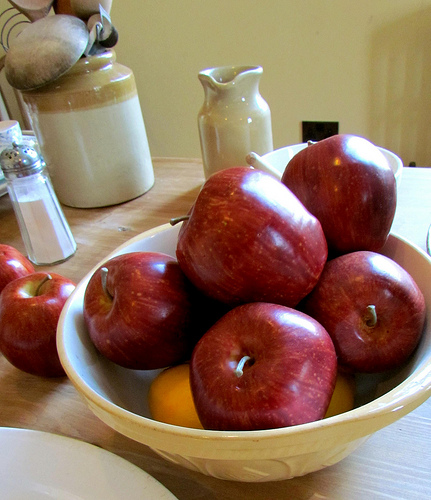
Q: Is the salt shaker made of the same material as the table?
A: No, the salt shaker is made of glass and the table is made of wood.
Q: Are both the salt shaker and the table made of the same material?
A: No, the salt shaker is made of glass and the table is made of wood.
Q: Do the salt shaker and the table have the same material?
A: No, the salt shaker is made of glass and the table is made of wood.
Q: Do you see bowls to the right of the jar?
A: Yes, there is a bowl to the right of the jar.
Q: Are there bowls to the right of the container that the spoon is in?
A: Yes, there is a bowl to the right of the jar.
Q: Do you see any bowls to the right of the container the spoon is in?
A: Yes, there is a bowl to the right of the jar.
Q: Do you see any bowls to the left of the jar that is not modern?
A: No, the bowl is to the right of the jar.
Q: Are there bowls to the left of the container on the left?
A: No, the bowl is to the right of the jar.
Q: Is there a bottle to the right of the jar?
A: No, there is a bowl to the right of the jar.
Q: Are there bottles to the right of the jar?
A: No, there is a bowl to the right of the jar.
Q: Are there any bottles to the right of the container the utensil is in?
A: No, there is a bowl to the right of the jar.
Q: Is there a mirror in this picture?
A: No, there are no mirrors.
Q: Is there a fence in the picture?
A: No, there are no fences.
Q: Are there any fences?
A: No, there are no fences.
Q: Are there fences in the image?
A: No, there are no fences.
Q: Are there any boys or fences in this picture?
A: No, there are no fences or boys.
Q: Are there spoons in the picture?
A: Yes, there is a spoon.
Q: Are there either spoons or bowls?
A: Yes, there is a spoon.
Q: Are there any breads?
A: No, there are no breads.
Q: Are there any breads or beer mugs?
A: No, there are no breads or beer mugs.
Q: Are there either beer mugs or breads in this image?
A: No, there are no breads or beer mugs.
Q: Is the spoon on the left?
A: Yes, the spoon is on the left of the image.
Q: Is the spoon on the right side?
A: No, the spoon is on the left of the image.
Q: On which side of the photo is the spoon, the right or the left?
A: The spoon is on the left of the image.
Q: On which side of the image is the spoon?
A: The spoon is on the left of the image.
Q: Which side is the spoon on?
A: The spoon is on the left of the image.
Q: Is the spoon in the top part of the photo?
A: Yes, the spoon is in the top of the image.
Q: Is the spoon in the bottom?
A: No, the spoon is in the top of the image.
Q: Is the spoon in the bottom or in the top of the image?
A: The spoon is in the top of the image.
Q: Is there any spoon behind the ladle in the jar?
A: Yes, there is a spoon behind the ladle.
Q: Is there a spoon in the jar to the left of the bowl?
A: Yes, there is a spoon in the jar.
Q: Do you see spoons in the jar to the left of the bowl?
A: Yes, there is a spoon in the jar.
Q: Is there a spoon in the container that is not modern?
A: Yes, there is a spoon in the jar.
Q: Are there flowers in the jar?
A: No, there is a spoon in the jar.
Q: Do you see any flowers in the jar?
A: No, there is a spoon in the jar.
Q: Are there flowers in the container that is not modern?
A: No, there is a spoon in the jar.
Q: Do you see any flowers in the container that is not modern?
A: No, there is a spoon in the jar.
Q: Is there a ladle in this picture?
A: Yes, there is a ladle.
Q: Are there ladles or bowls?
A: Yes, there is a ladle.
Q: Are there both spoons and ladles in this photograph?
A: Yes, there are both a ladle and a spoon.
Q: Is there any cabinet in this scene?
A: No, there are no cabinets.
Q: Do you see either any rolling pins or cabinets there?
A: No, there are no cabinets or rolling pins.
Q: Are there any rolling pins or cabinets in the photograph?
A: No, there are no cabinets or rolling pins.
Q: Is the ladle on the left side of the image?
A: Yes, the ladle is on the left of the image.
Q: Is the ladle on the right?
A: No, the ladle is on the left of the image.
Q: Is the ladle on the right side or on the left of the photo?
A: The ladle is on the left of the image.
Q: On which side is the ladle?
A: The ladle is on the left of the image.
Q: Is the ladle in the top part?
A: Yes, the ladle is in the top of the image.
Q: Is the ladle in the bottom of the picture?
A: No, the ladle is in the top of the image.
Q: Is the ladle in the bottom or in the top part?
A: The ladle is in the top of the image.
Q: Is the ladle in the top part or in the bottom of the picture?
A: The ladle is in the top of the image.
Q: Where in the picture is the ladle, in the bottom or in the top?
A: The ladle is in the top of the image.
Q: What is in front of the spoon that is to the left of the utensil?
A: The ladle is in front of the spoon.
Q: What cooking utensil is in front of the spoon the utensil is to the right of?
A: The cooking utensil is a ladle.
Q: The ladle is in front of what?
A: The ladle is in front of the spoon.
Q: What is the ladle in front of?
A: The ladle is in front of the spoon.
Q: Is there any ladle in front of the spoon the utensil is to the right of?
A: Yes, there is a ladle in front of the spoon.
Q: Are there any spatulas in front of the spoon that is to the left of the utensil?
A: No, there is a ladle in front of the spoon.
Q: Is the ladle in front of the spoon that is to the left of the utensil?
A: Yes, the ladle is in front of the spoon.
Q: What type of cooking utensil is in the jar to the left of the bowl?
A: The cooking utensil is a ladle.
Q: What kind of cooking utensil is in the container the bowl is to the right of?
A: The cooking utensil is a ladle.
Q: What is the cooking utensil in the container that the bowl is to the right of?
A: The cooking utensil is a ladle.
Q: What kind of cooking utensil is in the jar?
A: The cooking utensil is a ladle.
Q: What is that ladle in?
A: The ladle is in the jar.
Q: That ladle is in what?
A: The ladle is in the jar.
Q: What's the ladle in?
A: The ladle is in the jar.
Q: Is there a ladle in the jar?
A: Yes, there is a ladle in the jar.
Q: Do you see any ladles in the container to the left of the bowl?
A: Yes, there is a ladle in the jar.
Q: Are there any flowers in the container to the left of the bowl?
A: No, there is a ladle in the jar.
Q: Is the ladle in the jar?
A: Yes, the ladle is in the jar.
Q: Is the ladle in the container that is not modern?
A: Yes, the ladle is in the jar.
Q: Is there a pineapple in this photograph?
A: No, there are no pineapples.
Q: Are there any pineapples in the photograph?
A: No, there are no pineapples.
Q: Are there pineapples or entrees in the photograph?
A: No, there are no pineapples or entrees.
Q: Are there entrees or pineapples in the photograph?
A: No, there are no pineapples or entrees.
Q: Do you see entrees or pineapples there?
A: No, there are no pineapples or entrees.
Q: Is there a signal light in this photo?
A: No, there are no traffic lights.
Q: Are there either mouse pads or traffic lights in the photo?
A: No, there are no traffic lights or mouse pads.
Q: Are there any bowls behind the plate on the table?
A: Yes, there is a bowl behind the plate.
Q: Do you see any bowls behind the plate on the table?
A: Yes, there is a bowl behind the plate.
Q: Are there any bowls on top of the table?
A: Yes, there is a bowl on top of the table.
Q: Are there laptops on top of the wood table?
A: No, there is a bowl on top of the table.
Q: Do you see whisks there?
A: Yes, there is a whisk.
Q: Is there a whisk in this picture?
A: Yes, there is a whisk.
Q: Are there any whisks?
A: Yes, there is a whisk.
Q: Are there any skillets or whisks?
A: Yes, there is a whisk.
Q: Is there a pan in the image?
A: No, there are no pans.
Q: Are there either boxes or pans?
A: No, there are no pans or boxes.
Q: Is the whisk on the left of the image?
A: Yes, the whisk is on the left of the image.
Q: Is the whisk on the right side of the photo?
A: No, the whisk is on the left of the image.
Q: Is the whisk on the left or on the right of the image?
A: The whisk is on the left of the image.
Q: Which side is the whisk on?
A: The whisk is on the left of the image.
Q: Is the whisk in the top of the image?
A: Yes, the whisk is in the top of the image.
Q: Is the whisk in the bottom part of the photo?
A: No, the whisk is in the top of the image.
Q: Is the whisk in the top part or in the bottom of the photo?
A: The whisk is in the top of the image.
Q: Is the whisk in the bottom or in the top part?
A: The whisk is in the top of the image.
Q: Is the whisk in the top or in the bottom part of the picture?
A: The whisk is in the top of the image.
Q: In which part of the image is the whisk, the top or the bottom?
A: The whisk is in the top of the image.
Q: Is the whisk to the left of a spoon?
A: Yes, the whisk is to the left of a spoon.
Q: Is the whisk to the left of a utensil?
A: Yes, the whisk is to the left of a utensil.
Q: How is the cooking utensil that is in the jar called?
A: The cooking utensil is a whisk.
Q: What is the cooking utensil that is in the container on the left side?
A: The cooking utensil is a whisk.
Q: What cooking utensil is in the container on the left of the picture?
A: The cooking utensil is a whisk.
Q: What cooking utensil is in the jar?
A: The cooking utensil is a whisk.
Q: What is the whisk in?
A: The whisk is in the jar.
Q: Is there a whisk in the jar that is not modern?
A: Yes, there is a whisk in the jar.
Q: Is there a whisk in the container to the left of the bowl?
A: Yes, there is a whisk in the jar.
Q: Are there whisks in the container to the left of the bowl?
A: Yes, there is a whisk in the jar.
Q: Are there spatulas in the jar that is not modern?
A: No, there is a whisk in the jar.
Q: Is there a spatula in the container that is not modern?
A: No, there is a whisk in the jar.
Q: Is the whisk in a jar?
A: Yes, the whisk is in a jar.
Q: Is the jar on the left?
A: Yes, the jar is on the left of the image.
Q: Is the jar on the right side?
A: No, the jar is on the left of the image.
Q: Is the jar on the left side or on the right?
A: The jar is on the left of the image.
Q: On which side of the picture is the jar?
A: The jar is on the left of the image.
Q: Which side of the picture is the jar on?
A: The jar is on the left of the image.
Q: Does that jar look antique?
A: Yes, the jar is antique.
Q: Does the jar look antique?
A: Yes, the jar is antique.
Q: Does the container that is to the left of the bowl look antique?
A: Yes, the jar is antique.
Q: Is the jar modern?
A: No, the jar is antique.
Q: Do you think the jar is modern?
A: No, the jar is antique.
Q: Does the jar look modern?
A: No, the jar is antique.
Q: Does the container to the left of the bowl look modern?
A: No, the jar is antique.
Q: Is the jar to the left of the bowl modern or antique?
A: The jar is antique.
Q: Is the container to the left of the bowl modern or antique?
A: The jar is antique.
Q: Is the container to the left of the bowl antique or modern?
A: The jar is antique.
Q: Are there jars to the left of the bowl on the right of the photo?
A: Yes, there is a jar to the left of the bowl.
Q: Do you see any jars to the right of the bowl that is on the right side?
A: No, the jar is to the left of the bowl.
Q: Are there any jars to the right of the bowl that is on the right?
A: No, the jar is to the left of the bowl.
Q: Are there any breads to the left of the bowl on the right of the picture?
A: No, there is a jar to the left of the bowl.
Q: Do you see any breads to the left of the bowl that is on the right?
A: No, there is a jar to the left of the bowl.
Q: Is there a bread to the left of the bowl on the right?
A: No, there is a jar to the left of the bowl.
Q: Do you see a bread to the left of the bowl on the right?
A: No, there is a jar to the left of the bowl.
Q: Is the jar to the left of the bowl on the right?
A: Yes, the jar is to the left of the bowl.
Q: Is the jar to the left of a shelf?
A: No, the jar is to the left of the bowl.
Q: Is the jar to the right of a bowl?
A: No, the jar is to the left of a bowl.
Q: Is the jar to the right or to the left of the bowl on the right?
A: The jar is to the left of the bowl.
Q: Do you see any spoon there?
A: Yes, there is a spoon.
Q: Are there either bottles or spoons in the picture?
A: Yes, there is a spoon.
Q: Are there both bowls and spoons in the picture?
A: Yes, there are both a spoon and a bowl.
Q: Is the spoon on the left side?
A: Yes, the spoon is on the left of the image.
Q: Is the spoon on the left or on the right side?
A: The spoon is on the left of the image.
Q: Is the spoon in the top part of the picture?
A: Yes, the spoon is in the top of the image.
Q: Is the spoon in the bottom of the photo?
A: No, the spoon is in the top of the image.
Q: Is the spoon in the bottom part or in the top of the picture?
A: The spoon is in the top of the image.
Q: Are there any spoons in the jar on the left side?
A: Yes, there is a spoon in the jar.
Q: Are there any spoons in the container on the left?
A: Yes, there is a spoon in the jar.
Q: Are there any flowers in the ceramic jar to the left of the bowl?
A: No, there is a spoon in the jar.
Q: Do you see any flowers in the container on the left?
A: No, there is a spoon in the jar.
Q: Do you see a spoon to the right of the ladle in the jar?
A: Yes, there is a spoon to the right of the ladle.